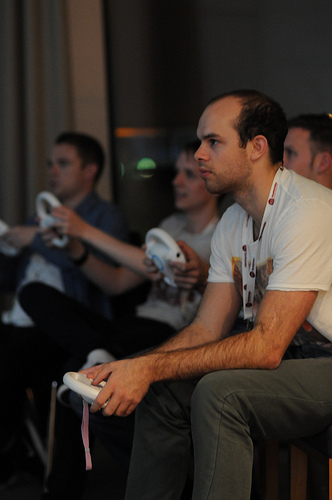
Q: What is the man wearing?
A: A t-shirt.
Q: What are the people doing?
A: Playing a video game.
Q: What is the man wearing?
A: Black pants and t-shirt.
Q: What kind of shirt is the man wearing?
A: A white t-shirt.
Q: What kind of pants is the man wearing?
A: Jeans.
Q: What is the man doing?
A: Playing a game.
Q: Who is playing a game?
A: Four people.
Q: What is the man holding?
A: A game controller.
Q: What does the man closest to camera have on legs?
A: Black jeans.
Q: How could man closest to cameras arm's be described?
A: Hairy.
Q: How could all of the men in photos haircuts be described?
A: Short.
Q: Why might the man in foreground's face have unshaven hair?
A: He's growing beard.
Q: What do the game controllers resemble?
A: Steering wheels.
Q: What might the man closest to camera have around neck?
A: Identification tag.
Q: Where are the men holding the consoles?
A: Sitting.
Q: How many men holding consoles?
A: Four.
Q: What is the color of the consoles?
A: White.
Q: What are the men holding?
A: Consoles.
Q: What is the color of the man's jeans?
A: Gray.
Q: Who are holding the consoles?
A: Men.